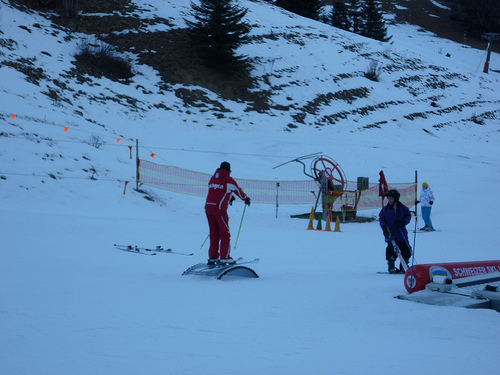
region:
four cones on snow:
[300, 205, 349, 235]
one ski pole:
[222, 195, 254, 266]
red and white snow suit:
[197, 165, 247, 260]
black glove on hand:
[237, 195, 252, 208]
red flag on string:
[6, 110, 160, 167]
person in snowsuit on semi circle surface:
[187, 152, 260, 289]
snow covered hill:
[2, 1, 497, 200]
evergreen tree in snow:
[173, 2, 263, 97]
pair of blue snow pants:
[415, 205, 436, 228]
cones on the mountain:
[305, 205, 342, 232]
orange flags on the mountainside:
[5, 101, 155, 170]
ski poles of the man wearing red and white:
[196, 202, 253, 257]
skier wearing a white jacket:
[414, 181, 436, 229]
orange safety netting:
[138, 153, 410, 213]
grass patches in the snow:
[55, 10, 390, 117]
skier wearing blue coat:
[376, 189, 418, 274]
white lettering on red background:
[449, 261, 494, 280]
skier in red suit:
[199, 158, 251, 270]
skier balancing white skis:
[192, 160, 259, 278]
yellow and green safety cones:
[303, 204, 343, 237]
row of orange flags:
[0, 110, 161, 165]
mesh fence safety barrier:
[130, 135, 423, 228]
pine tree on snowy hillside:
[178, 1, 259, 93]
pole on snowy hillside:
[472, 39, 497, 79]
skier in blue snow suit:
[376, 187, 421, 275]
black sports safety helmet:
[380, 187, 402, 199]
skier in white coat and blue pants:
[412, 180, 439, 236]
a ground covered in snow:
[101, 236, 180, 343]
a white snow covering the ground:
[37, 278, 172, 370]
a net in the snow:
[114, 123, 426, 252]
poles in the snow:
[123, 108, 480, 210]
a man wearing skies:
[164, 146, 254, 262]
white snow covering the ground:
[172, 13, 484, 180]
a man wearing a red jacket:
[185, 146, 282, 268]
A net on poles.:
[127, 132, 426, 210]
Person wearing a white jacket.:
[416, 180, 434, 210]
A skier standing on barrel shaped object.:
[180, 150, 260, 281]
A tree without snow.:
[145, 0, 270, 105]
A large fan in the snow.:
[304, 150, 362, 217]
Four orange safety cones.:
[296, 212, 346, 234]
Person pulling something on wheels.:
[376, 186, 498, 318]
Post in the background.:
[481, 36, 498, 71]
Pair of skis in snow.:
[114, 239, 189, 261]